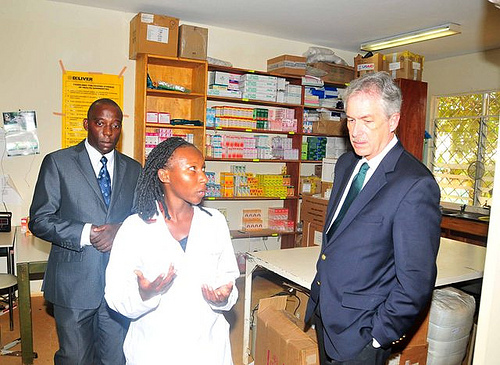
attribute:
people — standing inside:
[45, 71, 450, 351]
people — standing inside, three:
[6, 90, 459, 356]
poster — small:
[0, 105, 43, 157]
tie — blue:
[91, 161, 121, 203]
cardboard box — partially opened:
[250, 293, 428, 363]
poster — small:
[3, 104, 63, 166]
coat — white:
[102, 202, 252, 362]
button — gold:
[319, 254, 326, 260]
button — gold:
[313, 280, 320, 285]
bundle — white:
[430, 278, 480, 363]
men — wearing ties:
[21, 47, 497, 357]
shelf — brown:
[146, 82, 201, 102]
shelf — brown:
[142, 115, 202, 132]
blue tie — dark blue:
[323, 160, 375, 247]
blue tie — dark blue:
[92, 154, 114, 207]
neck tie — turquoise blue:
[324, 163, 366, 242]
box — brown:
[247, 291, 320, 363]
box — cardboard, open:
[124, 5, 181, 65]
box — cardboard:
[126, 10, 181, 63]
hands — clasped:
[88, 216, 117, 252]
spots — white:
[101, 178, 111, 192]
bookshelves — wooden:
[130, 48, 340, 184]